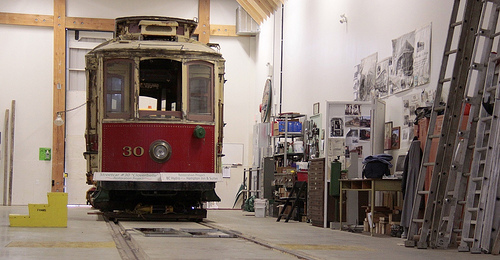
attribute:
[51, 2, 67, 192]
beams — large wooden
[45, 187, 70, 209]
stair — yellow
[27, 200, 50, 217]
stair — yellow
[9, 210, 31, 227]
stair — yellow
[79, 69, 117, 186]
door — large, white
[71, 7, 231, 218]
car — red 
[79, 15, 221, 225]
trolley — red, white, rusted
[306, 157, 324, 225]
tool cabinet — metal tool cabinet 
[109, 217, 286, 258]
train tracks/cement — cement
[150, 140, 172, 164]
headlight — single, large